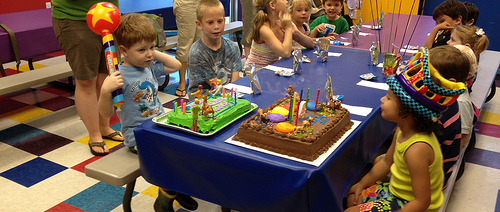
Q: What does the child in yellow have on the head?
A: Crown.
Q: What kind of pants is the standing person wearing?
A: Shorts.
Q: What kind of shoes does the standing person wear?
A: Sandals.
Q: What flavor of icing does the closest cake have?
A: Chocolate.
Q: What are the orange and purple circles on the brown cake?
A: Balloons.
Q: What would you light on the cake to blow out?
A: Candles.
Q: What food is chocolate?
A: Cake.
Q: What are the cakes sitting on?
A: A table.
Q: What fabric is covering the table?
A: A blue table cloth.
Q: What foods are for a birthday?
A: Cakes.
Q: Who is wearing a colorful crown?
A: Girl in yellow.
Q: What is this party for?
A: Child's birthday.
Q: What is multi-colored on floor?
A: Tiles.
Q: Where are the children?
A: Sitting in chairs.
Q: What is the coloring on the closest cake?
A: Chocolate brown.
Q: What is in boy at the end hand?
A: Toy.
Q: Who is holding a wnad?
A: Birthday boy.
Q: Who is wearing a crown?
A: Birthday girl.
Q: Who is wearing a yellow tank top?
A: A little girl.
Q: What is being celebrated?
A: Birthday.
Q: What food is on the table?
A: Cakes.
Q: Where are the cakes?
A: On the table.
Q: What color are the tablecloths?
A: Blue and purple.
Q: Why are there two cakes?
A: Two birthdays.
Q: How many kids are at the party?
A: 11.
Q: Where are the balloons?
A: On the chocolate cake.